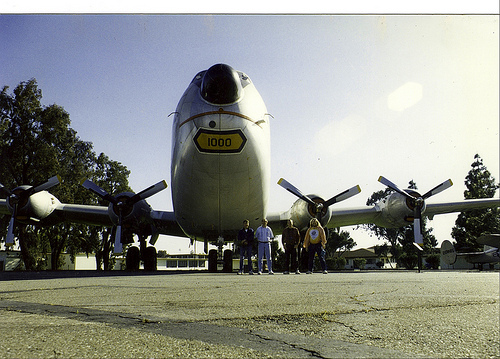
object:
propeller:
[377, 175, 453, 249]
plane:
[0, 61, 499, 272]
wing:
[0, 173, 178, 271]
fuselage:
[168, 108, 271, 246]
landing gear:
[124, 232, 158, 274]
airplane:
[0, 62, 500, 270]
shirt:
[281, 226, 302, 246]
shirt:
[253, 224, 275, 243]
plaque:
[194, 128, 247, 154]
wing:
[265, 178, 499, 272]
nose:
[197, 61, 242, 104]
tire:
[124, 246, 158, 272]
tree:
[0, 75, 137, 270]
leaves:
[0, 77, 136, 260]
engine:
[402, 189, 426, 212]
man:
[235, 215, 330, 275]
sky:
[1, 0, 497, 250]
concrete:
[0, 269, 500, 359]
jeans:
[236, 244, 255, 272]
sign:
[191, 126, 248, 155]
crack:
[243, 287, 412, 359]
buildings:
[0, 245, 499, 271]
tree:
[365, 152, 500, 271]